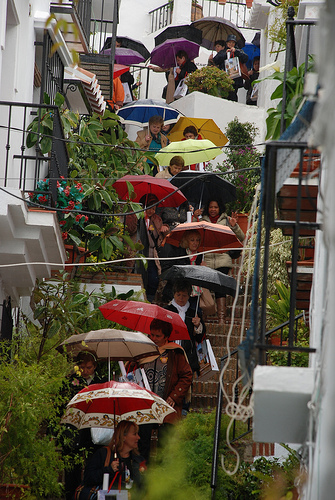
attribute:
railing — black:
[145, 1, 179, 29]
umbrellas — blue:
[110, 94, 215, 126]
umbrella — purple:
[144, 36, 205, 66]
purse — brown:
[78, 447, 132, 496]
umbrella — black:
[96, 154, 203, 211]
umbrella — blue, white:
[114, 94, 184, 125]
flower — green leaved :
[76, 181, 85, 192]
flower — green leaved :
[68, 199, 75, 208]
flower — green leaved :
[76, 212, 90, 222]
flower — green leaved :
[38, 194, 47, 201]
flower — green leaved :
[61, 229, 69, 241]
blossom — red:
[75, 213, 89, 221]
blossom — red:
[75, 180, 85, 193]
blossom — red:
[37, 193, 47, 202]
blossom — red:
[27, 190, 35, 196]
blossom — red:
[60, 217, 66, 226]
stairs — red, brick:
[191, 296, 252, 408]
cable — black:
[1, 164, 261, 221]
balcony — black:
[13, 96, 108, 213]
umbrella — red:
[95, 294, 196, 344]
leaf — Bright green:
[50, 451, 58, 458]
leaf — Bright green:
[36, 379, 48, 386]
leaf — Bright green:
[97, 237, 114, 259]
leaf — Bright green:
[48, 306, 61, 315]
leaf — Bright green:
[26, 339, 35, 346]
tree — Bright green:
[13, 328, 68, 489]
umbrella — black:
[104, 87, 187, 132]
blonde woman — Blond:
[135, 115, 168, 152]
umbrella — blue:
[115, 96, 183, 123]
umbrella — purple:
[148, 36, 202, 68]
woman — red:
[82, 417, 145, 496]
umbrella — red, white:
[59, 380, 176, 429]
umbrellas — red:
[103, 291, 186, 333]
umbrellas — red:
[66, 380, 167, 423]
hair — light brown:
[108, 419, 140, 457]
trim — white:
[112, 104, 180, 125]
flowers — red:
[26, 176, 89, 241]